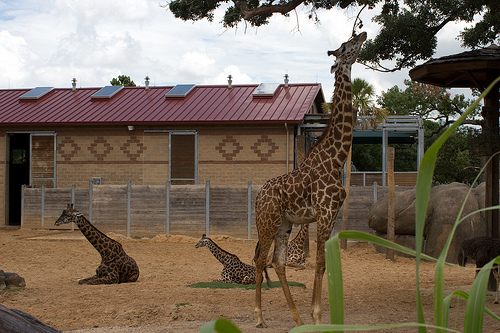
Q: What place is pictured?
A: It is a pen.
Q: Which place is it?
A: It is a pen.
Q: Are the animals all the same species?
A: Yes, all the animals are giraffes.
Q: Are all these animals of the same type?
A: Yes, all the animals are giraffes.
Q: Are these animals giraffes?
A: Yes, all the animals are giraffes.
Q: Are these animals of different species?
A: No, all the animals are giraffes.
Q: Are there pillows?
A: No, there are no pillows.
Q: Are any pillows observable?
A: No, there are no pillows.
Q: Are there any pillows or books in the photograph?
A: No, there are no pillows or books.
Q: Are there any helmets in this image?
A: No, there are no helmets.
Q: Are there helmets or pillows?
A: No, there are no helmets or pillows.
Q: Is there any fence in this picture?
A: Yes, there is a fence.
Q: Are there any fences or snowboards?
A: Yes, there is a fence.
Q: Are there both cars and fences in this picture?
A: No, there is a fence but no cars.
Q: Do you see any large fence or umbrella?
A: Yes, there is a large fence.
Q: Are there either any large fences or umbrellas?
A: Yes, there is a large fence.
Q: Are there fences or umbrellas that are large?
A: Yes, the fence is large.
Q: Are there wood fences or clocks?
A: Yes, there is a wood fence.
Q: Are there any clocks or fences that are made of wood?
A: Yes, the fence is made of wood.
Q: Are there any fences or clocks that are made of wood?
A: Yes, the fence is made of wood.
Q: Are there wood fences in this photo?
A: Yes, there is a wood fence.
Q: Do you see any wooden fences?
A: Yes, there is a wood fence.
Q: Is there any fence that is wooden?
A: Yes, there is a fence that is wooden.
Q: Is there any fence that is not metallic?
A: Yes, there is a wooden fence.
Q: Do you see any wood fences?
A: Yes, there is a fence that is made of wood.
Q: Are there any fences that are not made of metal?
A: Yes, there is a fence that is made of wood.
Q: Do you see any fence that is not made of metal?
A: Yes, there is a fence that is made of wood.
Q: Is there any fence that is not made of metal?
A: Yes, there is a fence that is made of wood.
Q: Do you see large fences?
A: Yes, there is a large fence.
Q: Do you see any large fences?
A: Yes, there is a large fence.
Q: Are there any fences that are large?
A: Yes, there is a fence that is large.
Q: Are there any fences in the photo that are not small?
A: Yes, there is a large fence.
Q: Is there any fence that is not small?
A: Yes, there is a large fence.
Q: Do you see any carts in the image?
A: No, there are no carts.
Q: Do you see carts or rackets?
A: No, there are no carts or rackets.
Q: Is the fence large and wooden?
A: Yes, the fence is large and wooden.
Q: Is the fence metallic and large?
A: No, the fence is large but wooden.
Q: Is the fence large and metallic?
A: No, the fence is large but wooden.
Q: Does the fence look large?
A: Yes, the fence is large.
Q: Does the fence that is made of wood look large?
A: Yes, the fence is large.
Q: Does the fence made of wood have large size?
A: Yes, the fence is large.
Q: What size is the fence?
A: The fence is large.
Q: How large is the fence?
A: The fence is large.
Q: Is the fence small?
A: No, the fence is large.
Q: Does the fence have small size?
A: No, the fence is large.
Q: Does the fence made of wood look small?
A: No, the fence is large.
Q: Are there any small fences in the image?
A: No, there is a fence but it is large.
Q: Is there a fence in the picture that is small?
A: No, there is a fence but it is large.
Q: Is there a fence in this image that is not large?
A: No, there is a fence but it is large.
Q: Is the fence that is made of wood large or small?
A: The fence is large.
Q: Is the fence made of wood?
A: Yes, the fence is made of wood.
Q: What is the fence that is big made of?
A: The fence is made of wood.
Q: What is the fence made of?
A: The fence is made of wood.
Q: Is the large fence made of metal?
A: No, the fence is made of wood.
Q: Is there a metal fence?
A: No, there is a fence but it is made of wood.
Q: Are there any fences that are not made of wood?
A: No, there is a fence but it is made of wood.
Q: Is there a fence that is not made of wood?
A: No, there is a fence but it is made of wood.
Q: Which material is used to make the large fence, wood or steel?
A: The fence is made of wood.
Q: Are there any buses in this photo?
A: No, there are no buses.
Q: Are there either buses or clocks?
A: No, there are no buses or clocks.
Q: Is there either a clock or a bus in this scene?
A: No, there are no buses or clocks.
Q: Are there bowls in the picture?
A: No, there are no bowls.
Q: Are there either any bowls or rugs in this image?
A: No, there are no bowls or rugs.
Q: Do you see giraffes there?
A: Yes, there is a giraffe.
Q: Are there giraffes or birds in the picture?
A: Yes, there is a giraffe.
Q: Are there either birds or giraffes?
A: Yes, there is a giraffe.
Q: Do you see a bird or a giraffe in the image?
A: Yes, there is a giraffe.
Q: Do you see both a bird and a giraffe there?
A: No, there is a giraffe but no birds.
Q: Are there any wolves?
A: No, there are no wolves.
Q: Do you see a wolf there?
A: No, there are no wolves.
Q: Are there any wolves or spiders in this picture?
A: No, there are no wolves or spiders.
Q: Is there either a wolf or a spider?
A: No, there are no wolves or spiders.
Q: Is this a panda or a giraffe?
A: This is a giraffe.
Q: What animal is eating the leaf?
A: The giraffe is eating the leaf.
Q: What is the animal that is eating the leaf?
A: The animal is a giraffe.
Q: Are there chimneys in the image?
A: No, there are no chimneys.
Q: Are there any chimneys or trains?
A: No, there are no chimneys or trains.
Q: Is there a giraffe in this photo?
A: Yes, there is a giraffe.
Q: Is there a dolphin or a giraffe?
A: Yes, there is a giraffe.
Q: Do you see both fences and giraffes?
A: Yes, there are both a giraffe and a fence.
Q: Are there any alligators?
A: No, there are no alligators.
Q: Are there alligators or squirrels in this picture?
A: No, there are no alligators or squirrels.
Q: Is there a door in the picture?
A: Yes, there is a door.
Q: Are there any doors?
A: Yes, there is a door.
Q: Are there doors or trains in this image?
A: Yes, there is a door.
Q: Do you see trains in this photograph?
A: No, there are no trains.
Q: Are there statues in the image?
A: No, there are no statues.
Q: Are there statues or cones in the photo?
A: No, there are no statues or cones.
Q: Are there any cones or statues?
A: No, there are no statues or cones.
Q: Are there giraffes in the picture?
A: Yes, there is a giraffe.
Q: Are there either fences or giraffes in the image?
A: Yes, there is a giraffe.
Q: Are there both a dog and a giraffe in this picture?
A: No, there is a giraffe but no dogs.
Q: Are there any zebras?
A: No, there are no zebras.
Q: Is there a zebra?
A: No, there are no zebras.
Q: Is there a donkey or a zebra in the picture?
A: No, there are no zebras or donkeys.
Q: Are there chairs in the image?
A: No, there are no chairs.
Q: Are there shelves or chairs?
A: No, there are no chairs or shelves.